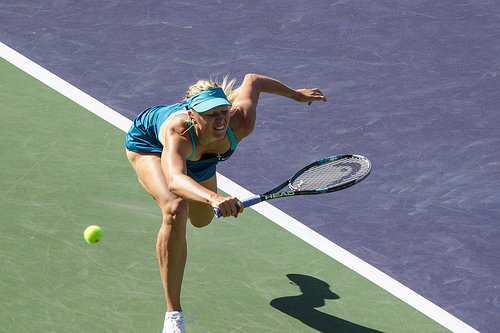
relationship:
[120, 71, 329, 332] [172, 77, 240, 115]
woman has visor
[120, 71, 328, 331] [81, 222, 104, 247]
woman swinging at ball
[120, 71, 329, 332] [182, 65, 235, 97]
woman has hair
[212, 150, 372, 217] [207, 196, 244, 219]
racket in hand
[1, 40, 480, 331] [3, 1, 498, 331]
line on court